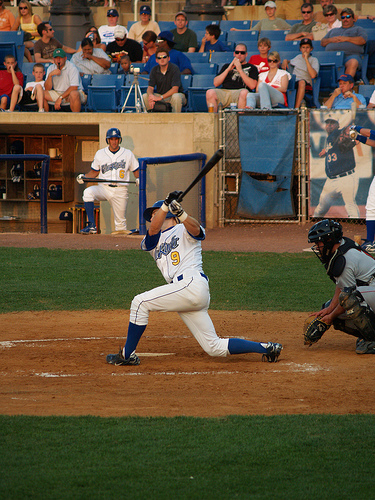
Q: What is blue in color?
A: The socks.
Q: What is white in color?
A: The pants.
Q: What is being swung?
A: The bat.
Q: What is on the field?
A: Grass.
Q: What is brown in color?
A: The dirt.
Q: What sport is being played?
A: Baseball.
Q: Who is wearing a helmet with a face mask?
A: Catcher.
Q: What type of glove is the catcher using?
A: Catcher's mitt.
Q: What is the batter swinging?
A: Bat.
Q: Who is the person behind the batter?
A: Catcher.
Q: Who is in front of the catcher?
A: Batter.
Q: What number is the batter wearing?
A: 9.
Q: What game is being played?
A: Baseball.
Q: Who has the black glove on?
A: Catcher.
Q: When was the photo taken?
A: During a game.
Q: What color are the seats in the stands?
A: Blue.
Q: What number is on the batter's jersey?
A: Nine.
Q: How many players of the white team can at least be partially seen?
A: Three.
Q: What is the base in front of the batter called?
A: Home plate.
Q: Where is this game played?
A: Baseball field.